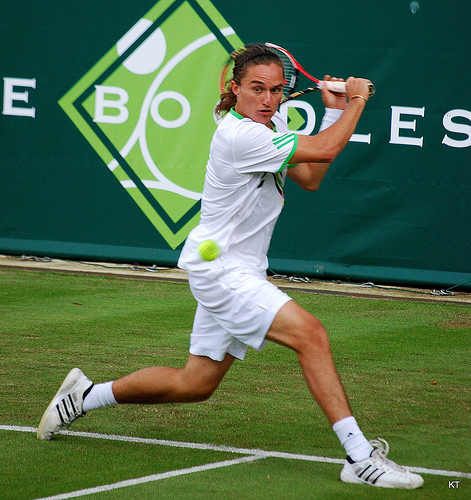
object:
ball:
[198, 238, 220, 261]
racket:
[219, 41, 377, 118]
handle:
[314, 77, 376, 96]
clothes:
[182, 108, 299, 363]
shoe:
[343, 440, 427, 488]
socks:
[81, 375, 122, 417]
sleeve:
[234, 120, 299, 176]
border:
[280, 130, 299, 179]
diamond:
[59, 3, 305, 249]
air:
[155, 222, 176, 274]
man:
[37, 46, 425, 488]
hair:
[215, 49, 285, 113]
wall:
[340, 18, 447, 78]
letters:
[440, 107, 468, 148]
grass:
[80, 295, 126, 338]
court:
[8, 262, 462, 496]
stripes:
[52, 394, 84, 429]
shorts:
[181, 239, 293, 364]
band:
[346, 95, 370, 99]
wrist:
[345, 94, 369, 107]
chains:
[25, 248, 147, 276]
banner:
[5, 25, 166, 271]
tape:
[330, 80, 338, 93]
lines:
[368, 465, 390, 484]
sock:
[329, 410, 384, 453]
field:
[39, 272, 191, 358]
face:
[230, 63, 285, 122]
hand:
[345, 75, 368, 102]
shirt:
[177, 113, 297, 270]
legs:
[191, 271, 373, 450]